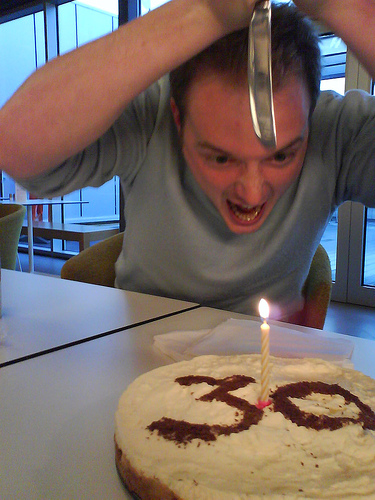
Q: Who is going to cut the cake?
A: The man.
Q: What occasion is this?
A: A birthday.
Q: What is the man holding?
A: A knife.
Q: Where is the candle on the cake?
A: In the center.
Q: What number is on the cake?
A: 30.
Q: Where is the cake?
A: On the counter.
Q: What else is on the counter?
A: Napkins.